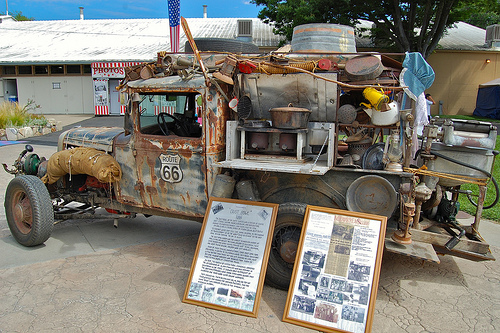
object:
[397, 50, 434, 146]
blue apron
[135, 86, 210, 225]
door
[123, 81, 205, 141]
window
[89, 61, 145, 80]
sign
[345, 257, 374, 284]
photo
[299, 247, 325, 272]
photo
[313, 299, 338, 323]
photo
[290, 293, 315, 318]
photo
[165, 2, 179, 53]
flag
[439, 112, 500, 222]
grass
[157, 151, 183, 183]
logo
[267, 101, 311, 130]
pot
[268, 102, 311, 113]
lid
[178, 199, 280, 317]
frame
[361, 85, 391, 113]
coffeepot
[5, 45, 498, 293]
truck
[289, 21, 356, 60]
basin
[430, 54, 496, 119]
wall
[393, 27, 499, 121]
building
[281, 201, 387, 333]
collage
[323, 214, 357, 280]
newspaper clipping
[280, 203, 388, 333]
sign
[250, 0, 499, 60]
tree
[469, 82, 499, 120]
tent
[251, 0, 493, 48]
leaves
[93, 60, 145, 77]
photos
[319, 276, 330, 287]
photo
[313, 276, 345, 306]
photo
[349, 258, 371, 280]
photo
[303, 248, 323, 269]
photo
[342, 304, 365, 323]
photo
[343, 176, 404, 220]
bucket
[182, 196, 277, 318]
sign